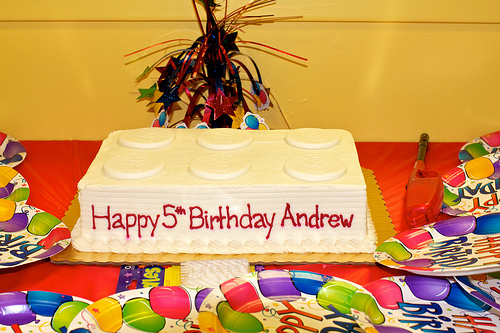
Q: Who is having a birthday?
A: Andrew.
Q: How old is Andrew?
A: Five.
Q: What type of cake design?
A: Lego.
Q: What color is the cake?
A: White.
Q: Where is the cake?
A: On table.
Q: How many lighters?
A: ONE.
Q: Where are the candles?
A: In pack on table.